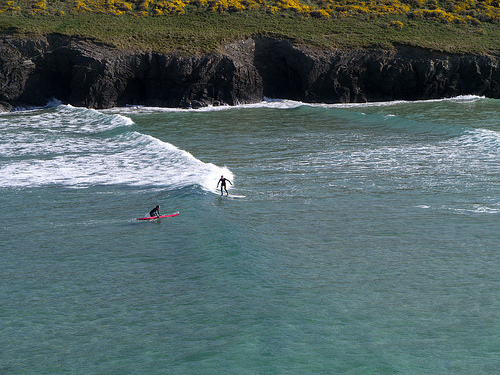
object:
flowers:
[386, 20, 403, 30]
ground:
[0, 0, 499, 57]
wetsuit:
[149, 209, 161, 218]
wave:
[0, 130, 242, 205]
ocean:
[0, 92, 499, 375]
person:
[216, 175, 232, 196]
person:
[150, 205, 161, 219]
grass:
[0, 0, 499, 64]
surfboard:
[136, 213, 180, 220]